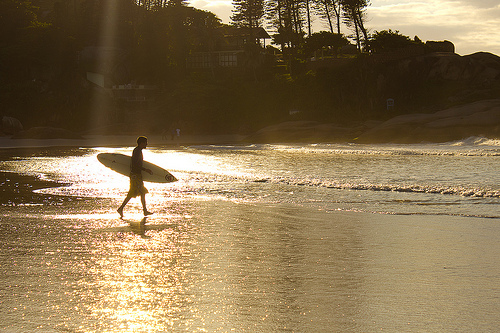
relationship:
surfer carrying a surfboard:
[116, 134, 153, 219] [98, 151, 180, 183]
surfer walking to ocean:
[116, 134, 153, 219] [203, 134, 480, 331]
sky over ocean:
[371, 1, 484, 41] [234, 140, 474, 330]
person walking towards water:
[113, 136, 157, 219] [208, 128, 494, 210]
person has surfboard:
[113, 136, 157, 219] [92, 144, 181, 189]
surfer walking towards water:
[116, 134, 156, 222] [208, 128, 494, 210]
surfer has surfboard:
[116, 134, 156, 222] [92, 148, 179, 189]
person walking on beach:
[113, 136, 153, 225] [16, 140, 494, 324]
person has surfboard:
[113, 136, 153, 225] [95, 146, 182, 190]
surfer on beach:
[116, 134, 153, 219] [16, 140, 494, 324]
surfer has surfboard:
[116, 134, 153, 219] [98, 150, 174, 185]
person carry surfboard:
[113, 136, 157, 219] [92, 148, 179, 189]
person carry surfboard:
[113, 136, 157, 219] [92, 144, 181, 189]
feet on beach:
[108, 203, 153, 219] [4, 184, 498, 331]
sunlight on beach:
[84, 234, 171, 332] [4, 184, 498, 331]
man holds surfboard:
[115, 135, 159, 216] [92, 148, 177, 193]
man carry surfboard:
[115, 128, 151, 220] [92, 148, 179, 189]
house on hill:
[157, 4, 498, 71] [4, 4, 498, 145]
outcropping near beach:
[308, 21, 497, 90] [28, 134, 498, 206]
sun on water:
[157, 143, 220, 172] [13, 135, 480, 209]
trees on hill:
[222, 1, 376, 48] [4, 4, 498, 145]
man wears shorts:
[115, 135, 159, 216] [124, 179, 149, 199]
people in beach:
[153, 117, 193, 144] [61, 126, 250, 155]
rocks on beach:
[4, 110, 84, 139] [8, 152, 497, 321]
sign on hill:
[377, 94, 398, 110] [4, 4, 498, 145]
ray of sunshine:
[59, 150, 100, 186] [62, 157, 87, 182]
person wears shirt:
[168, 121, 180, 137] [173, 126, 180, 136]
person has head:
[113, 136, 157, 219] [134, 136, 148, 149]